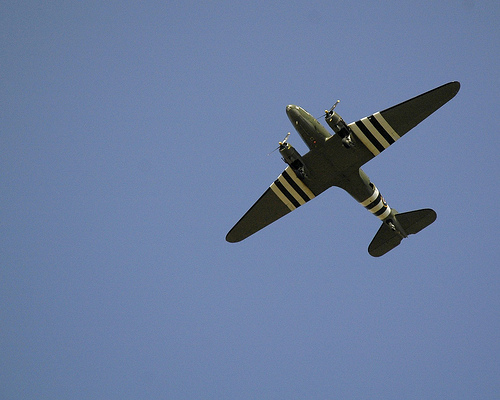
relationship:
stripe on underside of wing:
[370, 107, 400, 147] [344, 79, 462, 167]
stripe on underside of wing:
[346, 110, 401, 159] [344, 79, 462, 167]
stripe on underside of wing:
[284, 165, 315, 203] [225, 165, 331, 245]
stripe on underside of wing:
[268, 165, 314, 213] [225, 165, 331, 245]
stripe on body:
[355, 185, 382, 209] [345, 166, 395, 224]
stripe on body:
[358, 186, 389, 222] [345, 166, 395, 224]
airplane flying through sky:
[223, 81, 463, 259] [81, 82, 200, 185]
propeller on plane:
[270, 129, 294, 157] [225, 77, 463, 257]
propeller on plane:
[314, 99, 346, 125] [225, 77, 463, 257]